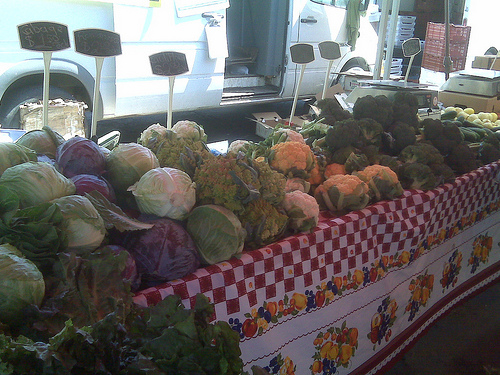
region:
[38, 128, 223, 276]
lettuce and cabbage on the table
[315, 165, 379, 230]
Cauliflower head on the table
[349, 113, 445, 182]
A pile of brocoli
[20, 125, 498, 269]
A table full of veggies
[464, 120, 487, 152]
cucumber or zuchini by the broccoli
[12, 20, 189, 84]
black signs for the price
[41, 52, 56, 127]
A white stand for the sign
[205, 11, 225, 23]
handle of the van door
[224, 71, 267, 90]
A step in the van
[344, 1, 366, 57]
A shirt hanging on the mirror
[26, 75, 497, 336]
a table with vegetables on it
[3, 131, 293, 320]
green and purple cabbage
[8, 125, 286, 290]
purple and green cabbage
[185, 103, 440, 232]
white and yellow cauliflower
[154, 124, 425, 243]
yellow and white cauliflower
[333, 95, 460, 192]
green broccoli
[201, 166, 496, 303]
red and white checkered table cloth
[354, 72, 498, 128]
two silver scales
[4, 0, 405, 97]
a white van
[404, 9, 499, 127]
a stack of red crates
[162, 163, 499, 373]
A fruit and checkered table cloth.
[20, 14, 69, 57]
A $1.50 cabbage sale sign.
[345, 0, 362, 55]
A green hanging towel.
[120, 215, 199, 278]
A large purple cabbage on bottom of stack.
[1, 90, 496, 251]
A row of vegetables for sale.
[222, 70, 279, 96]
A step on a truck.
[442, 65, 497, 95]
A silver measuring scale.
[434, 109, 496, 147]
A pile of cucumbers.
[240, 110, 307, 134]
A box laying on the street.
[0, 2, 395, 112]
A white delivery truck.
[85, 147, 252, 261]
plenty vegetables are visible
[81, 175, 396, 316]
plenty vegetables are visible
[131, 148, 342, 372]
plenty vegetables are visible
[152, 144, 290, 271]
plenty vegetables are visible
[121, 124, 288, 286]
plenty vegetables are visible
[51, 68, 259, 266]
plenty vegetables are visible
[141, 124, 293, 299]
plenty vegetables are visible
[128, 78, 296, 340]
plenty vegetables are visible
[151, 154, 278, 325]
plenty vegetables are visible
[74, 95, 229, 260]
plenty vegetables are visible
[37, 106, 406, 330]
the vegetables are visible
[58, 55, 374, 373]
the vegetables are visible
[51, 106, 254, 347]
the vegetables are visible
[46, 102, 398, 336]
the vegetables are visible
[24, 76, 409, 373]
the vegetables are visible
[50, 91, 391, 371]
the vegetables are visible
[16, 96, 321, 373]
the vegetables are visible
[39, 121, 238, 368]
the vegetables are visible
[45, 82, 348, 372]
the vegetables are visible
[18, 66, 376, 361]
the vegetables are visible